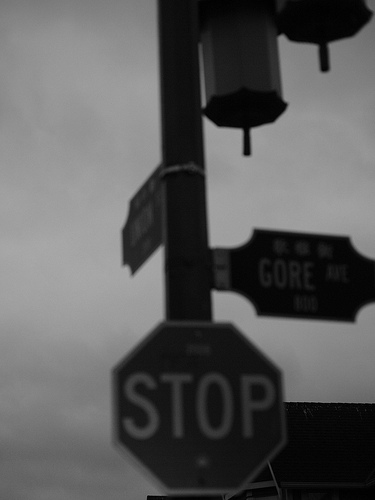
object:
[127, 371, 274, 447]
stop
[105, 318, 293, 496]
sign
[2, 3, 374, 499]
sky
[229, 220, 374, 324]
sign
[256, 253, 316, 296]
gore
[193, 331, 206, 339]
screw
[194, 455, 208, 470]
screw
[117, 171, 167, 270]
road sign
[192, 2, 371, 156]
lamps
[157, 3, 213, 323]
pole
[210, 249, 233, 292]
hinge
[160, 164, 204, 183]
hinge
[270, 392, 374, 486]
roof